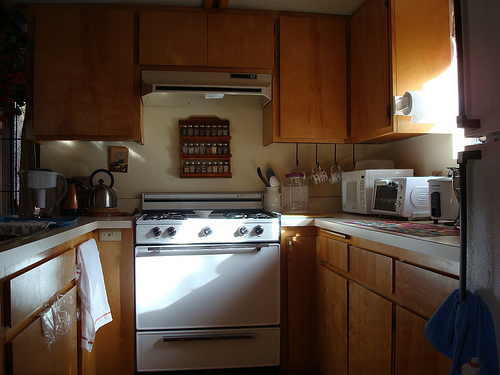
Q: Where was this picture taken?
A: A kitchen.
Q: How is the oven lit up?
A: By the sun shining through the window.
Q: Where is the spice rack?
A: On the wall above the oven.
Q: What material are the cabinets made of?
A: Wood.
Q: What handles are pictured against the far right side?
A: Refrigerator handles.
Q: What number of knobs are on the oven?
A: Five.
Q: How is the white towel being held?
A: By a wooden drawer.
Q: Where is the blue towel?
A: Stuffed through the refrigerator handle.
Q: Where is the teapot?
A: On the counter left of the oven.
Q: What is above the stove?
A: Spice rack.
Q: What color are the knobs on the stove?
A: Black.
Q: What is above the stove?
A: A spice rack.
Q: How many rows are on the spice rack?
A: 3.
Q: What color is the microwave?
A: White.